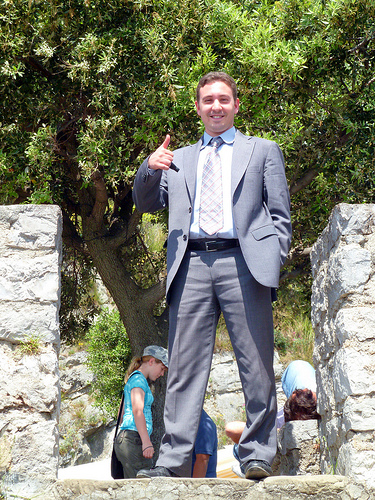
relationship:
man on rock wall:
[131, 70, 293, 477] [0, 198, 375, 499]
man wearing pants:
[131, 70, 293, 477] [152, 237, 280, 472]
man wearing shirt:
[131, 70, 293, 477] [190, 126, 237, 239]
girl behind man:
[113, 343, 167, 478] [131, 70, 293, 477]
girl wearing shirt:
[113, 343, 167, 478] [120, 371, 156, 437]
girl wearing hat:
[113, 343, 167, 478] [139, 345, 168, 369]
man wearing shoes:
[131, 70, 293, 477] [133, 457, 271, 480]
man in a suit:
[131, 70, 293, 477] [126, 126, 297, 474]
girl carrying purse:
[113, 343, 167, 478] [94, 393, 127, 491]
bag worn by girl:
[111, 380, 134, 477] [113, 343, 167, 478]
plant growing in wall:
[16, 333, 47, 358] [0, 204, 57, 497]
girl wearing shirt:
[113, 343, 167, 478] [117, 367, 155, 435]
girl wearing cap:
[113, 343, 167, 478] [141, 343, 171, 366]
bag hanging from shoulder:
[111, 380, 134, 477] [127, 373, 147, 386]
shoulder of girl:
[127, 373, 147, 386] [113, 343, 167, 478]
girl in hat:
[113, 343, 167, 478] [142, 341, 168, 367]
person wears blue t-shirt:
[192, 408, 218, 477] [188, 405, 222, 483]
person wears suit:
[192, 408, 218, 477] [126, 126, 297, 474]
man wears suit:
[131, 70, 293, 477] [126, 126, 297, 474]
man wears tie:
[131, 70, 293, 477] [201, 135, 227, 236]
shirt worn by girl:
[117, 367, 155, 435] [113, 343, 167, 478]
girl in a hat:
[113, 343, 167, 478] [142, 343, 172, 368]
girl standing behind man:
[113, 343, 167, 478] [131, 70, 293, 477]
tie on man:
[197, 137, 223, 235] [131, 70, 293, 477]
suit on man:
[126, 126, 297, 474] [131, 70, 293, 477]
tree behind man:
[0, 1, 375, 467] [107, 64, 312, 490]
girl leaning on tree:
[118, 343, 194, 471] [0, 1, 375, 467]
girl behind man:
[118, 343, 194, 471] [131, 70, 293, 477]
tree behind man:
[0, 1, 375, 467] [131, 70, 293, 477]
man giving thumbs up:
[131, 70, 293, 477] [142, 135, 178, 177]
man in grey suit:
[131, 70, 293, 477] [131, 133, 294, 331]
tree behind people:
[0, 1, 375, 467] [87, 64, 333, 456]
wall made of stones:
[0, 203, 63, 498] [9, 256, 52, 300]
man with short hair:
[131, 70, 293, 477] [194, 69, 240, 100]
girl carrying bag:
[113, 343, 167, 478] [111, 380, 134, 477]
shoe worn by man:
[237, 457, 277, 477] [126, 65, 304, 481]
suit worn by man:
[126, 126, 297, 474] [126, 65, 304, 481]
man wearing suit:
[131, 70, 293, 477] [150, 132, 286, 462]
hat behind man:
[138, 345, 170, 372] [131, 70, 293, 477]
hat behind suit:
[138, 345, 170, 372] [150, 132, 286, 462]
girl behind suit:
[113, 343, 167, 478] [150, 132, 286, 462]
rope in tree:
[24, 23, 83, 183] [8, 19, 370, 360]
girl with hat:
[113, 343, 167, 478] [138, 345, 170, 372]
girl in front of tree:
[113, 343, 167, 478] [8, 19, 370, 360]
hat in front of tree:
[138, 345, 170, 372] [8, 19, 370, 360]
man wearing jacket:
[131, 70, 293, 477] [131, 127, 293, 304]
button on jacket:
[187, 204, 192, 214] [131, 127, 293, 304]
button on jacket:
[180, 233, 187, 241] [131, 127, 293, 304]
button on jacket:
[140, 171, 149, 182] [131, 127, 293, 304]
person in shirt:
[114, 343, 167, 486] [118, 369, 153, 433]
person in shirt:
[192, 408, 218, 477] [190, 409, 216, 478]